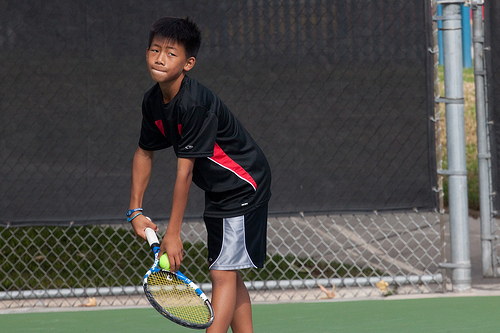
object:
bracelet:
[126, 208, 144, 217]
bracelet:
[126, 212, 142, 222]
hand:
[157, 237, 184, 273]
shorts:
[203, 203, 268, 271]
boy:
[125, 15, 271, 332]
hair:
[148, 16, 203, 60]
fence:
[0, 0, 449, 313]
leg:
[206, 269, 237, 332]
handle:
[143, 216, 160, 247]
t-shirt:
[138, 76, 272, 218]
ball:
[158, 252, 170, 270]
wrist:
[165, 228, 181, 238]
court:
[0, 295, 499, 332]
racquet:
[143, 216, 215, 329]